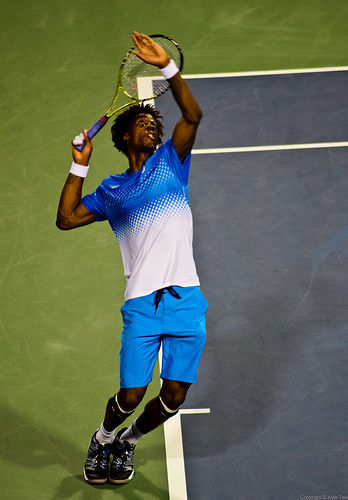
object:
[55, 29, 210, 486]
man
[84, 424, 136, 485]
shoes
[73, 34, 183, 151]
tennis racket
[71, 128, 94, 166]
handle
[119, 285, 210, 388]
shorts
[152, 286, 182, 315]
drawstring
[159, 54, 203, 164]
arm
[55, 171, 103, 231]
arm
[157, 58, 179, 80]
wristband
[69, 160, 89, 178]
wristband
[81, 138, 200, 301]
shirt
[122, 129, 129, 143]
ear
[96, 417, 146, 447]
socks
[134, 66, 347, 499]
lines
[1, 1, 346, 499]
tennis court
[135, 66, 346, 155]
lines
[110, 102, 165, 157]
hair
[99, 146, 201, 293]
torso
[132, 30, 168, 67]
left hand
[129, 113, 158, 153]
face